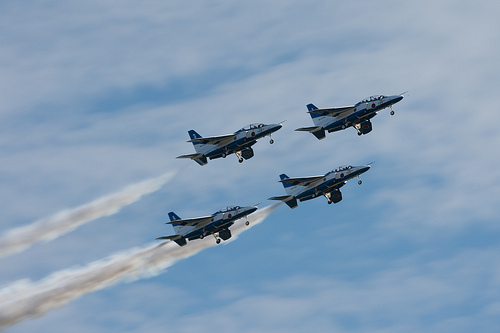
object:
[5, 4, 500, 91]
sky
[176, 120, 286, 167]
airplane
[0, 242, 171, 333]
smoke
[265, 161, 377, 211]
airplane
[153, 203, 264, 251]
airplane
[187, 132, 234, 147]
wing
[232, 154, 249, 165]
wheel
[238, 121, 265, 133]
cockpit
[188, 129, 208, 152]
tail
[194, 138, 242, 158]
side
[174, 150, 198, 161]
hind wing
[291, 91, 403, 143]
airplane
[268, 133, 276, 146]
wheel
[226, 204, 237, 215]
pilot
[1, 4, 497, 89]
cloud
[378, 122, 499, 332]
cloud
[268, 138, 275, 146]
tire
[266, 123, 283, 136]
nose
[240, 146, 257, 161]
landing gear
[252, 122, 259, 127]
pilot